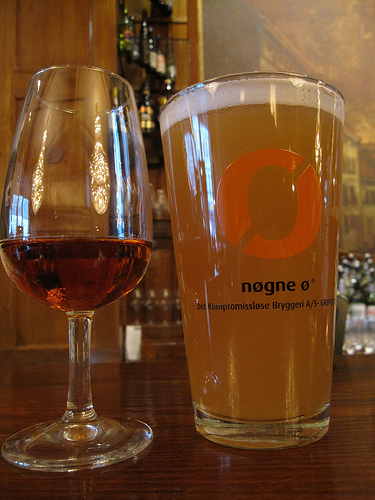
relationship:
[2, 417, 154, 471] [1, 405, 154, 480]
bottom of glass